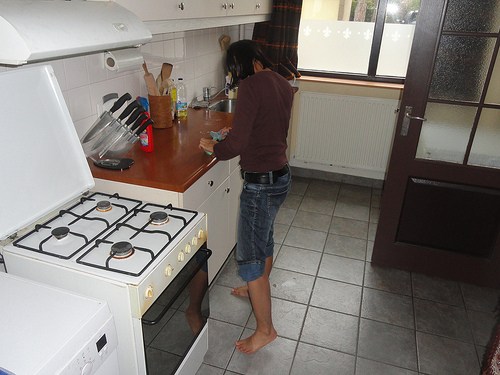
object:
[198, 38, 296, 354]
woman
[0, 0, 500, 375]
kitchen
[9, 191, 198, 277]
stove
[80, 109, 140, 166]
knife block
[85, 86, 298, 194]
counter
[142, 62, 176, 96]
cooking utensils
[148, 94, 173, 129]
container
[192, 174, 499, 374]
floor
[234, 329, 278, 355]
left foot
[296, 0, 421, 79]
window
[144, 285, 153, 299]
knob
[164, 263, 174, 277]
knob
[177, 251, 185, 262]
knob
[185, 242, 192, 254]
knob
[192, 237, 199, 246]
knob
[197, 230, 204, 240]
knob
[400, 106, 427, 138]
handle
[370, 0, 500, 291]
door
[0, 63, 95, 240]
cover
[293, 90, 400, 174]
wall heater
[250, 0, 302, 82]
curtains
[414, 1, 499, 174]
windows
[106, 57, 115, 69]
towel dispenser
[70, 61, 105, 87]
wall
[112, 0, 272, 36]
cabinets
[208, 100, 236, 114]
sink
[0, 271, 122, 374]
dishwasher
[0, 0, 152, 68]
range hood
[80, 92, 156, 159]
knives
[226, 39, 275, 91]
hair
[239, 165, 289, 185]
belt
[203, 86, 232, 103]
faucet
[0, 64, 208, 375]
oven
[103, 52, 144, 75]
paper towel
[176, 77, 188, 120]
bottle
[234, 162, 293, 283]
jeans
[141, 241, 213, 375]
door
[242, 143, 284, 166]
waist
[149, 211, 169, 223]
burner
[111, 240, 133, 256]
burner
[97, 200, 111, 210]
burner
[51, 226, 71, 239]
burner